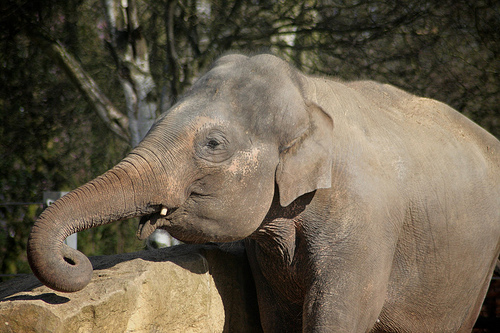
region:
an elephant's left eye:
[205, 132, 225, 152]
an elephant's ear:
[280, 100, 335, 201]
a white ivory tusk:
[157, 199, 169, 219]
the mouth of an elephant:
[138, 186, 197, 236]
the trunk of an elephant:
[26, 135, 162, 295]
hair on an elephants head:
[227, 45, 287, 57]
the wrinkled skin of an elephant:
[407, 199, 444, 276]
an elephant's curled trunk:
[20, 175, 110, 296]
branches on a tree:
[247, 8, 432, 53]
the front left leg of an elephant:
[303, 245, 390, 327]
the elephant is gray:
[28, 52, 498, 332]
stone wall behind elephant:
[0, 241, 262, 331]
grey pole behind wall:
[44, 190, 77, 257]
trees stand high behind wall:
[2, 0, 498, 265]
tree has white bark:
[32, 0, 317, 252]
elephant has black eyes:
[201, 132, 221, 155]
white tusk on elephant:
[158, 204, 168, 219]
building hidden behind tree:
[0, 3, 322, 183]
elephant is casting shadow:
[7, 245, 262, 330]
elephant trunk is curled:
[21, 141, 159, 290]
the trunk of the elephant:
[29, 106, 180, 296]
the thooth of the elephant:
[154, 199, 170, 219]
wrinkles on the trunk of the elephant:
[25, 132, 183, 308]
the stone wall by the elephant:
[88, 246, 245, 329]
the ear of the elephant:
[271, 80, 339, 213]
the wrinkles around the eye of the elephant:
[192, 126, 241, 163]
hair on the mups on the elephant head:
[213, 44, 299, 87]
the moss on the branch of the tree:
[45, 27, 122, 139]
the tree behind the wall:
[82, 2, 499, 92]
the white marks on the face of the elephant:
[227, 147, 269, 214]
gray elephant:
[16, 23, 499, 331]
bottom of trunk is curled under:
[21, 161, 165, 303]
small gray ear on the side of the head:
[272, 106, 349, 213]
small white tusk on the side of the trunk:
[154, 204, 172, 218]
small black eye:
[202, 136, 229, 155]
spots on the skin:
[122, 135, 204, 212]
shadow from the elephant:
[200, 240, 271, 332]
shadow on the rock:
[4, 286, 68, 306]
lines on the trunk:
[107, 131, 182, 210]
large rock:
[3, 259, 257, 331]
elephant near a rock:
[16, 58, 486, 323]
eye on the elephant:
[192, 128, 234, 163]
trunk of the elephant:
[8, 196, 111, 286]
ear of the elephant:
[270, 89, 353, 199]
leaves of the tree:
[422, 27, 448, 47]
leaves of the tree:
[44, 100, 86, 139]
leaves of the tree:
[25, 25, 40, 47]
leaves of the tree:
[371, 54, 416, 81]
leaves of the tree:
[310, 19, 352, 42]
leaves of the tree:
[332, 18, 367, 40]